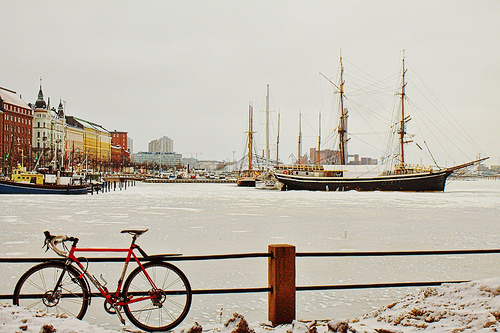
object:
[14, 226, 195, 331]
bike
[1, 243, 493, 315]
fence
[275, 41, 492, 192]
ship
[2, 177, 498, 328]
water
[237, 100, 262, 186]
ship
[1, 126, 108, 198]
ship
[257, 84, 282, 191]
ship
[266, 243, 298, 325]
post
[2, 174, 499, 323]
snow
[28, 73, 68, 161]
building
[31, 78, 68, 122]
spires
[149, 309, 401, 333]
rocks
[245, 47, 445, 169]
masts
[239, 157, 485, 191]
ships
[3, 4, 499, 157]
sky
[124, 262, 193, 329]
tire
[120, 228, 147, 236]
seat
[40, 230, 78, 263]
handle bars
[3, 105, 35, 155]
windows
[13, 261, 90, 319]
wheel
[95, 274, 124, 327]
pedals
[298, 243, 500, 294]
cables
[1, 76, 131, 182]
buildings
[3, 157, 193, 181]
pier